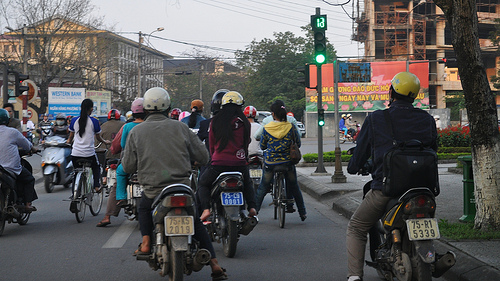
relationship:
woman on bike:
[252, 91, 311, 223] [267, 167, 292, 226]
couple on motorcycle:
[204, 92, 257, 222] [193, 182, 254, 246]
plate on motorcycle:
[219, 190, 245, 208] [193, 182, 254, 246]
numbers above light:
[311, 15, 327, 28] [312, 49, 324, 64]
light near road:
[312, 49, 324, 64] [0, 139, 449, 281]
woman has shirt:
[54, 92, 109, 205] [55, 118, 97, 159]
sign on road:
[47, 80, 87, 124] [0, 139, 449, 281]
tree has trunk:
[456, 8, 500, 234] [471, 109, 500, 227]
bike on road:
[267, 167, 292, 226] [0, 139, 449, 281]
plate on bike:
[219, 190, 245, 208] [267, 167, 292, 226]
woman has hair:
[54, 92, 109, 205] [77, 97, 105, 140]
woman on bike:
[54, 92, 109, 205] [71, 165, 101, 219]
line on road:
[96, 222, 134, 257] [229, 207, 341, 273]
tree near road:
[456, 8, 500, 234] [0, 139, 449, 281]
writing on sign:
[318, 88, 390, 101] [303, 78, 431, 112]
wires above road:
[239, 0, 327, 52] [0, 139, 449, 281]